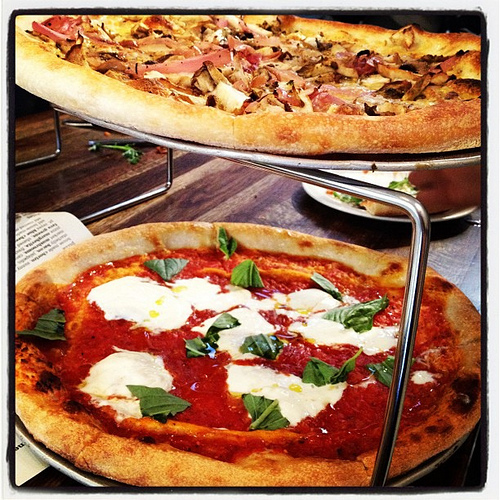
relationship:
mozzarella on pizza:
[76, 275, 434, 428] [4, 221, 482, 483]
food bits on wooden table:
[84, 139, 146, 170] [57, 151, 257, 216]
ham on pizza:
[137, 49, 231, 76] [13, 9, 476, 153]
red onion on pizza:
[317, 88, 347, 106] [13, 9, 476, 153]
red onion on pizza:
[32, 22, 67, 43] [13, 9, 476, 153]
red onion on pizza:
[228, 37, 239, 49] [13, 9, 476, 153]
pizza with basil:
[4, 221, 482, 483] [227, 254, 266, 290]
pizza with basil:
[4, 221, 482, 483] [123, 380, 193, 420]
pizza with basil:
[4, 221, 482, 483] [236, 388, 291, 433]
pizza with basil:
[4, 221, 482, 483] [12, 300, 69, 350]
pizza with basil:
[4, 221, 482, 483] [317, 290, 392, 337]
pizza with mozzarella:
[4, 221, 482, 483] [76, 275, 434, 428]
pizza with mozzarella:
[4, 221, 482, 483] [83, 270, 400, 360]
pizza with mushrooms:
[13, 9, 476, 153] [26, 15, 481, 115]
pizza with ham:
[13, 9, 476, 153] [27, 14, 464, 114]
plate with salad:
[301, 182, 358, 219] [375, 172, 413, 190]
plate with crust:
[301, 182, 358, 219] [323, 197, 426, 230]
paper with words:
[11, 194, 96, 280] [28, 219, 49, 248]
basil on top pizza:
[144, 257, 190, 280] [4, 221, 482, 483]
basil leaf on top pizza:
[217, 226, 237, 260] [9, 12, 496, 172]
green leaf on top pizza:
[306, 260, 343, 302] [317, 165, 431, 223]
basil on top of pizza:
[322, 293, 389, 332] [4, 221, 482, 483]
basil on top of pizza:
[241, 393, 290, 430] [4, 221, 482, 483]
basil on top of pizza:
[231, 258, 265, 288] [4, 221, 482, 483]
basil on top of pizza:
[144, 257, 190, 280] [4, 221, 482, 483]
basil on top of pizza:
[125, 384, 192, 417] [4, 221, 482, 483]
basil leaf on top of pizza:
[217, 226, 237, 260] [4, 221, 482, 483]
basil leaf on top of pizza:
[230, 259, 265, 287] [4, 221, 482, 483]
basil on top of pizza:
[16, 309, 68, 341] [4, 221, 482, 483]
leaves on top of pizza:
[302, 334, 364, 385] [4, 221, 482, 483]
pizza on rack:
[13, 9, 476, 153] [11, 102, 488, 489]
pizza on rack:
[4, 221, 482, 483] [11, 102, 488, 489]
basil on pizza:
[125, 384, 192, 417] [4, 221, 482, 483]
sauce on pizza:
[187, 363, 216, 398] [4, 221, 482, 483]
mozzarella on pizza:
[82, 272, 404, 429] [4, 221, 482, 483]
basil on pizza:
[21, 227, 394, 428] [4, 221, 482, 483]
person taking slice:
[412, 169, 482, 221] [319, 169, 415, 217]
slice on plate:
[319, 169, 415, 217] [295, 179, 475, 222]